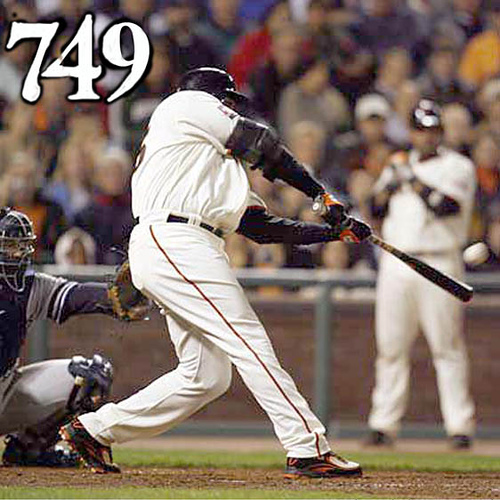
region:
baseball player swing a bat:
[62, 63, 487, 477]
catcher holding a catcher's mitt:
[0, 205, 152, 450]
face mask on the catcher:
[7, 201, 41, 300]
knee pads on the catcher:
[72, 331, 125, 449]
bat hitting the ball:
[309, 179, 480, 329]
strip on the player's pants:
[135, 225, 306, 444]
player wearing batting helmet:
[408, 89, 455, 159]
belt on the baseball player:
[127, 195, 245, 246]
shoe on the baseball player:
[287, 13, 379, 134]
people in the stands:
[295, 18, 404, 157]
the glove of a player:
[311, 190, 348, 227]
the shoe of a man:
[280, 455, 365, 483]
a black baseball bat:
[318, 204, 475, 305]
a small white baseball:
[462, 242, 490, 267]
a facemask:
[0, 208, 36, 290]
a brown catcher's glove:
[108, 260, 158, 319]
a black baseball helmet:
[172, 64, 254, 109]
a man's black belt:
[134, 214, 223, 238]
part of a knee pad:
[63, 355, 114, 410]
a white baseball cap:
[353, 91, 391, 124]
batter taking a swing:
[64, 30, 481, 485]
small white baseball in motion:
[460, 235, 490, 264]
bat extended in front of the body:
[239, 147, 499, 302]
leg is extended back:
[54, 317, 210, 487]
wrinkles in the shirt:
[147, 150, 229, 210]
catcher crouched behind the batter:
[0, 189, 203, 477]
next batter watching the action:
[349, 71, 490, 446]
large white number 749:
[5, 12, 168, 117]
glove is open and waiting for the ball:
[100, 245, 157, 331]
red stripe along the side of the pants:
[153, 227, 322, 441]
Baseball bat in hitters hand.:
[323, 196, 459, 303]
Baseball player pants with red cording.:
[106, 224, 311, 455]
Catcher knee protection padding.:
[60, 338, 115, 409]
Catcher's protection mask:
[2, 206, 35, 291]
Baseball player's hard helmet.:
[181, 55, 252, 112]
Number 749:
[5, 10, 155, 112]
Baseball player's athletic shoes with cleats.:
[50, 416, 356, 473]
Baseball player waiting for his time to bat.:
[365, 100, 476, 445]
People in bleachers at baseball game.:
[267, 5, 401, 170]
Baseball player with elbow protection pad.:
[216, 120, 303, 181]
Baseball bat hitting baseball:
[378, 237, 491, 309]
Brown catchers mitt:
[105, 261, 130, 321]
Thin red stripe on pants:
[166, 246, 181, 281]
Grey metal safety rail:
[311, 290, 328, 435]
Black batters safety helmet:
[406, 102, 439, 127]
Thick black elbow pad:
[240, 118, 282, 168]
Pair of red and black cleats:
[60, 421, 123, 477]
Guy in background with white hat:
[355, 93, 390, 136]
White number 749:
[6, 14, 155, 116]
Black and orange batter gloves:
[321, 192, 364, 249]